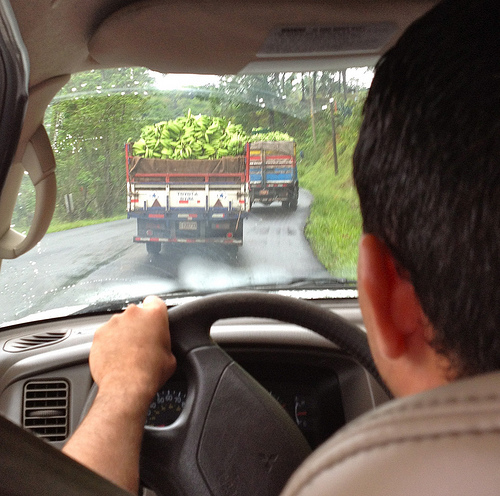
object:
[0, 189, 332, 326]
road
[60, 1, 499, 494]
man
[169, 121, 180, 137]
bundle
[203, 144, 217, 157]
bundle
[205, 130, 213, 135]
banana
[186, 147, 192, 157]
banana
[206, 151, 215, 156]
banana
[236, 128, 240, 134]
banana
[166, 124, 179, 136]
banana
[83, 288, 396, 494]
steering wheel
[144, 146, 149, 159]
green bananas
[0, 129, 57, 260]
white handle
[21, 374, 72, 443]
vent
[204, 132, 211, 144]
bananas trailer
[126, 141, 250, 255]
car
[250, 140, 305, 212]
car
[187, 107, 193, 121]
bananas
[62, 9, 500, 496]
person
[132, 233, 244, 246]
bumper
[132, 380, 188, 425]
speedometer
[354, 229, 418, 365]
ear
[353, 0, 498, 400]
head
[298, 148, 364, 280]
grass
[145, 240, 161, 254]
wheel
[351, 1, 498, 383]
hair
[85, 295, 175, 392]
hand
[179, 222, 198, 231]
liscence plate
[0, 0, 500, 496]
car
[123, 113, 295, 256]
back